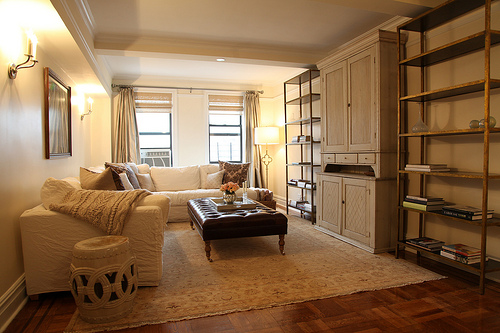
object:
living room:
[0, 1, 498, 332]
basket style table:
[63, 230, 144, 323]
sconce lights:
[6, 29, 39, 81]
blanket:
[45, 185, 151, 236]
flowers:
[225, 181, 231, 189]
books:
[438, 242, 486, 256]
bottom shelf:
[391, 226, 500, 285]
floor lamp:
[246, 125, 284, 210]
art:
[43, 66, 78, 159]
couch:
[99, 158, 278, 221]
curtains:
[111, 81, 143, 165]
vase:
[467, 114, 497, 134]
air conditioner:
[136, 147, 176, 171]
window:
[135, 92, 174, 169]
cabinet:
[312, 170, 399, 254]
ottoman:
[185, 192, 296, 261]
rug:
[67, 199, 452, 331]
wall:
[2, 0, 109, 329]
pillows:
[77, 156, 141, 193]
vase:
[220, 191, 239, 203]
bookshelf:
[392, 2, 500, 295]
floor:
[4, 274, 492, 332]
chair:
[19, 183, 172, 308]